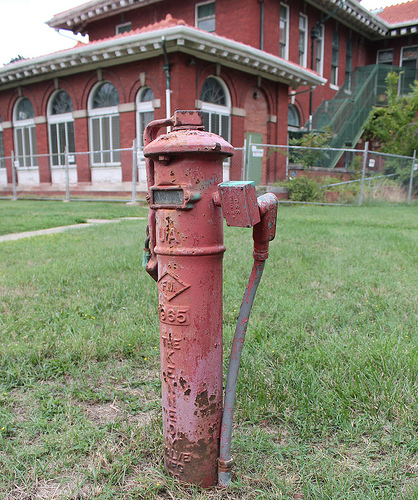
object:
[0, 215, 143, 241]
concrete pathway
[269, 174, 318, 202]
bush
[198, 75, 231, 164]
window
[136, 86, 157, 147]
window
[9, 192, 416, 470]
field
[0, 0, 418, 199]
house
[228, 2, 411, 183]
wall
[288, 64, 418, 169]
staircase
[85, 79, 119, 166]
window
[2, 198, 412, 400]
lot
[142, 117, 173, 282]
handle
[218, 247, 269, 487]
pipe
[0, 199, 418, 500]
ground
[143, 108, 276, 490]
fire hydrant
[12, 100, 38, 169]
window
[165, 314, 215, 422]
paint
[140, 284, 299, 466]
area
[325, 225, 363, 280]
grass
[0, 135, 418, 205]
fencing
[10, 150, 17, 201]
pole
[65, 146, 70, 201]
pole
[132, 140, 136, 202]
pole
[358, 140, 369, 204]
pole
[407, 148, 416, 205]
pole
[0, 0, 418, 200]
building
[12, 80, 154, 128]
arched windows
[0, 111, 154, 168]
narrow windows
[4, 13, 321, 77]
shingles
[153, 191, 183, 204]
panel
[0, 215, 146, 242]
walkway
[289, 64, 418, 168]
stairwaay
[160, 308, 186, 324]
lettering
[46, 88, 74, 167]
window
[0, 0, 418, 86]
roof